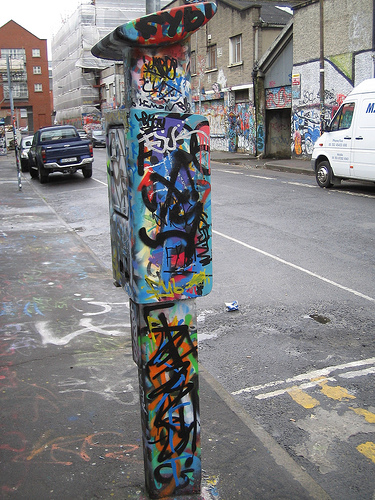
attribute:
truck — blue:
[19, 124, 95, 178]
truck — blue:
[27, 126, 95, 182]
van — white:
[310, 70, 374, 187]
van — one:
[316, 76, 373, 188]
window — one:
[25, 44, 41, 60]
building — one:
[186, 21, 296, 159]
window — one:
[198, 35, 223, 82]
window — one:
[183, 50, 202, 82]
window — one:
[29, 58, 45, 77]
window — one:
[29, 83, 46, 96]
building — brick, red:
[1, 15, 55, 130]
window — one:
[9, 79, 30, 102]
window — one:
[3, 83, 24, 103]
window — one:
[200, 40, 218, 74]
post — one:
[102, 29, 214, 499]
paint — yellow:
[276, 363, 374, 442]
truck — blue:
[28, 121, 98, 187]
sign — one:
[285, 68, 301, 102]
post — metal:
[3, 55, 29, 192]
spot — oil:
[297, 299, 334, 329]